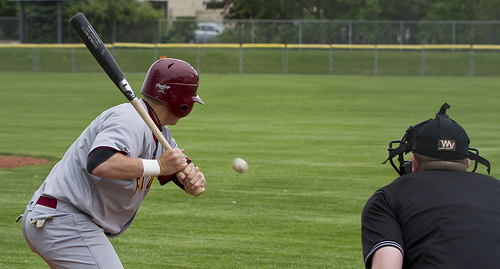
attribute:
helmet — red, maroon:
[140, 57, 206, 121]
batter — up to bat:
[19, 53, 208, 269]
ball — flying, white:
[229, 152, 252, 177]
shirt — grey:
[30, 96, 193, 243]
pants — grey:
[16, 190, 126, 268]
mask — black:
[386, 125, 492, 175]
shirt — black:
[360, 167, 498, 268]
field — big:
[2, 73, 498, 269]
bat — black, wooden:
[68, 12, 207, 199]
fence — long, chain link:
[1, 14, 499, 80]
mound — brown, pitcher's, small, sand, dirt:
[1, 152, 55, 172]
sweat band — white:
[139, 155, 163, 180]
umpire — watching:
[359, 102, 499, 269]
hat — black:
[410, 114, 472, 161]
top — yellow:
[0, 42, 499, 53]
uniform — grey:
[15, 96, 192, 268]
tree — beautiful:
[65, 2, 160, 44]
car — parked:
[193, 19, 225, 44]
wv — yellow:
[437, 133, 458, 156]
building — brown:
[151, 0, 324, 31]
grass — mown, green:
[1, 50, 498, 266]